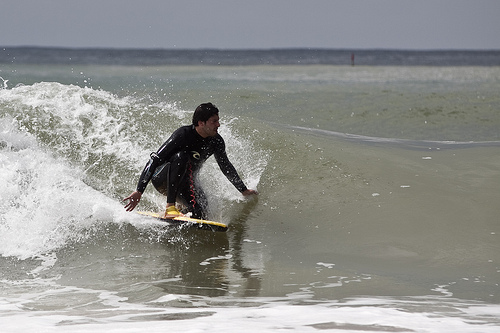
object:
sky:
[146, 11, 305, 43]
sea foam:
[33, 87, 127, 249]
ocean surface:
[381, 44, 476, 119]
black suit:
[132, 124, 248, 221]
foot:
[164, 202, 186, 221]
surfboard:
[130, 197, 283, 267]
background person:
[348, 52, 357, 62]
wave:
[0, 79, 168, 256]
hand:
[243, 187, 259, 197]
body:
[121, 100, 262, 225]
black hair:
[191, 101, 220, 126]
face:
[203, 111, 222, 134]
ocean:
[0, 46, 500, 329]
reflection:
[159, 227, 255, 308]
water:
[0, 44, 500, 333]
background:
[0, 2, 498, 73]